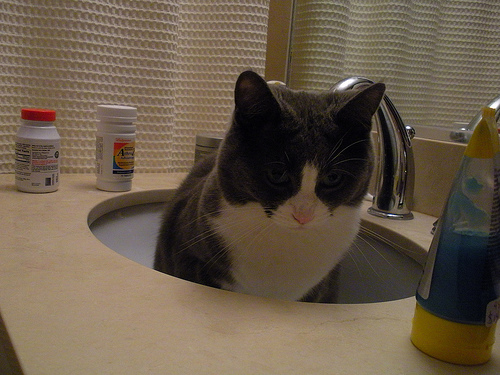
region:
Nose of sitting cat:
[290, 205, 320, 225]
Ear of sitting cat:
[225, 62, 278, 124]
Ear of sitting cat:
[342, 74, 384, 124]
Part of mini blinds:
[82, 30, 177, 76]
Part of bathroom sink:
[20, 255, 112, 323]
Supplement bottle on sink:
[9, 100, 64, 198]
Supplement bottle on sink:
[88, 99, 143, 192]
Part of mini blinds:
[352, 21, 423, 60]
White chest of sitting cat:
[246, 228, 321, 266]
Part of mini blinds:
[446, 60, 489, 104]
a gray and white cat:
[108, 25, 400, 370]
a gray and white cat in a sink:
[166, 58, 458, 356]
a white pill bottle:
[79, 96, 166, 195]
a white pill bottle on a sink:
[68, 85, 182, 243]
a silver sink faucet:
[310, 69, 427, 241]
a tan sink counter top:
[41, 150, 225, 344]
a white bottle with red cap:
[6, 100, 81, 197]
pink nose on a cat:
[251, 188, 332, 242]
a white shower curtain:
[1, 3, 281, 175]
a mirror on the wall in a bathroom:
[273, 8, 495, 168]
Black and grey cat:
[150, 70, 385, 305]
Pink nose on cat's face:
[290, 200, 315, 225]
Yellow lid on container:
[410, 300, 495, 366]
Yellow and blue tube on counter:
[410, 105, 495, 365]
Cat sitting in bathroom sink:
[85, 67, 430, 302]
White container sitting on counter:
[92, 100, 132, 190]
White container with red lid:
[12, 105, 57, 191]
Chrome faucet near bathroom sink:
[330, 75, 415, 220]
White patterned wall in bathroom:
[1, 0, 266, 170]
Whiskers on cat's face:
[165, 191, 295, 283]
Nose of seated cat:
[290, 205, 320, 226]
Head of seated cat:
[210, 61, 390, 237]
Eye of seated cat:
[317, 167, 352, 187]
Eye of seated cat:
[256, 162, 291, 187]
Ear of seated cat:
[229, 62, 289, 135]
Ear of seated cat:
[332, 72, 389, 133]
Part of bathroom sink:
[10, 219, 74, 279]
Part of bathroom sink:
[151, 324, 244, 369]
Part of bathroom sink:
[302, 331, 406, 373]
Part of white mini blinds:
[31, 18, 103, 56]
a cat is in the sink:
[154, 62, 408, 319]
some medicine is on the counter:
[12, 102, 149, 196]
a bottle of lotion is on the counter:
[401, 107, 493, 369]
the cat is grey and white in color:
[182, 62, 367, 304]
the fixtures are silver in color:
[326, 66, 437, 248]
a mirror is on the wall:
[267, 0, 494, 192]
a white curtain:
[13, 5, 227, 152]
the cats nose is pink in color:
[285, 200, 322, 227]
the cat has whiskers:
[176, 200, 395, 293]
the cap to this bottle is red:
[18, 99, 58, 123]